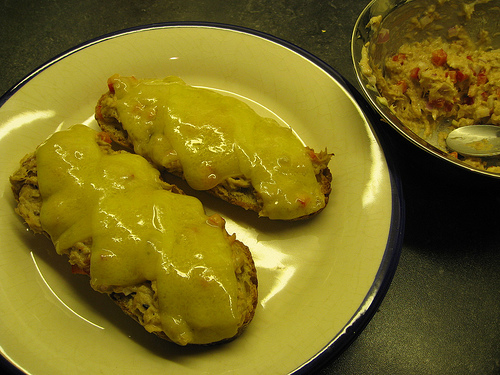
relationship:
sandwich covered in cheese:
[102, 73, 345, 216] [130, 85, 313, 201]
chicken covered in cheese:
[15, 76, 338, 343] [40, 137, 242, 307]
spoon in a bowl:
[450, 113, 499, 159] [353, 3, 500, 177]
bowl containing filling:
[353, 3, 500, 177] [391, 31, 497, 120]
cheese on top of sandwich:
[130, 85, 313, 201] [102, 73, 345, 216]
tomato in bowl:
[432, 47, 447, 65] [353, 3, 500, 177]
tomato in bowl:
[393, 52, 406, 64] [353, 3, 500, 177]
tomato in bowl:
[447, 70, 464, 84] [353, 3, 500, 177]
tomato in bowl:
[434, 100, 456, 112] [353, 3, 500, 177]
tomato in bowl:
[475, 73, 489, 89] [353, 3, 500, 177]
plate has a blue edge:
[4, 23, 398, 374] [2, 21, 407, 371]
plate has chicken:
[4, 23, 398, 374] [15, 76, 338, 343]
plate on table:
[4, 23, 398, 374] [5, 4, 488, 372]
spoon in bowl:
[450, 113, 499, 159] [353, 3, 500, 177]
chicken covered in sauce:
[15, 76, 338, 343] [40, 76, 326, 311]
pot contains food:
[353, 3, 500, 177] [391, 31, 497, 120]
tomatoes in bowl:
[432, 47, 447, 65] [353, 3, 500, 177]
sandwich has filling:
[102, 73, 345, 216] [391, 31, 497, 120]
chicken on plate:
[15, 76, 338, 343] [4, 23, 398, 374]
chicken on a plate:
[102, 73, 345, 216] [4, 23, 398, 374]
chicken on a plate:
[15, 76, 338, 343] [4, 23, 398, 374]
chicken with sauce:
[102, 73, 345, 216] [40, 76, 326, 311]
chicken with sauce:
[15, 76, 338, 343] [40, 76, 326, 311]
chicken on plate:
[15, 76, 338, 311] [4, 23, 398, 374]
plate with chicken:
[4, 23, 398, 374] [15, 76, 338, 311]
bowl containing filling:
[353, 3, 500, 177] [361, 4, 496, 165]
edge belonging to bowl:
[346, 0, 484, 180] [353, 3, 500, 177]